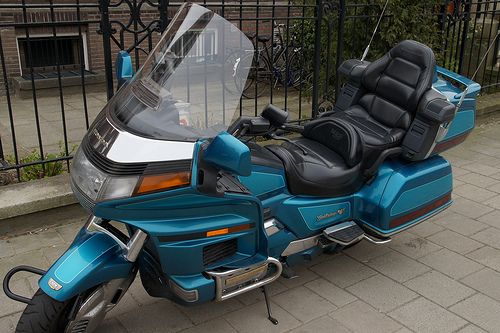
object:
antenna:
[426, 28, 500, 158]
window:
[17, 33, 91, 76]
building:
[1, 0, 304, 101]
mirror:
[114, 49, 133, 81]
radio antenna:
[358, 0, 395, 62]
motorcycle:
[0, 0, 482, 333]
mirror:
[202, 130, 254, 177]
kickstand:
[259, 285, 278, 326]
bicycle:
[230, 21, 311, 99]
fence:
[0, 2, 499, 187]